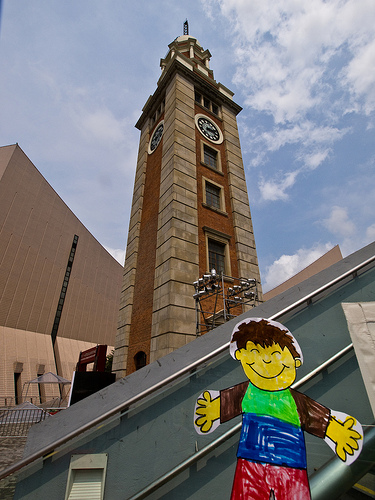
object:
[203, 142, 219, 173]
window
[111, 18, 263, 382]
clock tower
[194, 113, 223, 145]
clock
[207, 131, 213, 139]
numeral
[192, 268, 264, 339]
metal structure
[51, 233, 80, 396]
bar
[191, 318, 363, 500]
figure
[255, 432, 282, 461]
marker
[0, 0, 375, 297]
sky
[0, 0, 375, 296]
clouds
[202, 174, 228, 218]
door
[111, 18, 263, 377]
building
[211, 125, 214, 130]
numeral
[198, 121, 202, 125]
numeral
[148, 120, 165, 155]
clock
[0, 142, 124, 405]
building